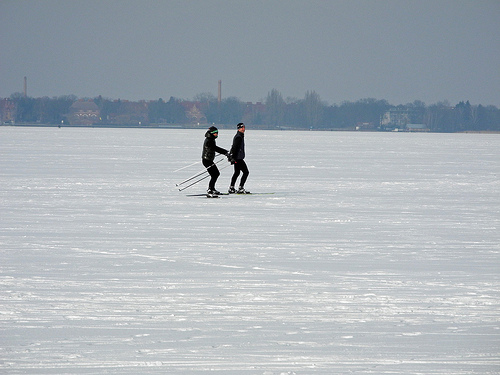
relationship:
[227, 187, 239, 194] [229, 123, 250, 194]
foot of a man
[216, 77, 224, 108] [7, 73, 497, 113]
smokestack on horizon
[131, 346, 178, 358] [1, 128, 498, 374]
foot print on top of snow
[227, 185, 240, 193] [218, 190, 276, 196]
boot on top of ski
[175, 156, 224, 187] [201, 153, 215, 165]
ski pole on hand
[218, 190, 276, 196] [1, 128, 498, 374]
ski in snow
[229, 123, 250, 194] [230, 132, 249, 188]
man wearing clothing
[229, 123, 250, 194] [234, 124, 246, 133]
man has head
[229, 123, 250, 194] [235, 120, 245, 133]
man has head